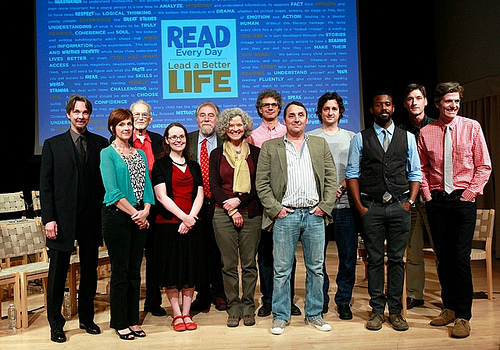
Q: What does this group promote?
A: Reading.